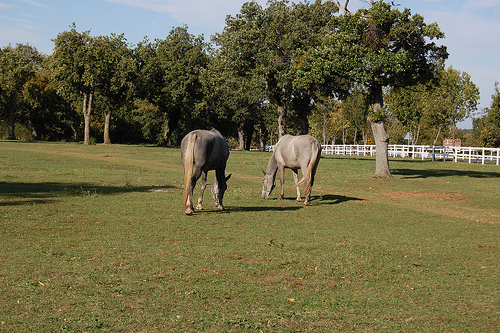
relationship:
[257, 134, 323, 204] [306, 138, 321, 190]
horse has tail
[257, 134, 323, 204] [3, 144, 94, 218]
horse eating grass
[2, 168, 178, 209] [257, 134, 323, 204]
shadow of horse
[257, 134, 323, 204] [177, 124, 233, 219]
horse by horse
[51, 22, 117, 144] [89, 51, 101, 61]
tree with leaves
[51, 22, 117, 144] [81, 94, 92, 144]
tree has trunk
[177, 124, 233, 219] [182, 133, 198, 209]
horse has tail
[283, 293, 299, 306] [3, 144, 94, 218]
leaf in grass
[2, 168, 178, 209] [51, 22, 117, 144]
shadow by tree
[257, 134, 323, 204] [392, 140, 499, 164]
horse surrounded by fence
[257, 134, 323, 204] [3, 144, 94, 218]
horse grazes on grass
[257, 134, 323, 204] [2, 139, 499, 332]
horse in field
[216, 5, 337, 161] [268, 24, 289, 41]
tree with leaves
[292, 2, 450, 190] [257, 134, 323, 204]
tree next to horse